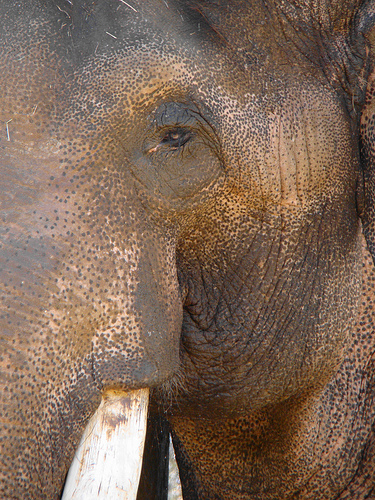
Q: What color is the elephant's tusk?
A: White.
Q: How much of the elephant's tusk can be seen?
A: Half.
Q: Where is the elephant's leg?
A: Right.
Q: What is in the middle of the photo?
A: Eye.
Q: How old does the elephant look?
A: Old.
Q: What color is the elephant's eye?
A: Black.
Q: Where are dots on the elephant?
A: Trunk.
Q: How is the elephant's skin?
A: Wrinkly.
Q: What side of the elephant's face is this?
A: Left.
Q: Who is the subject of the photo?
A: Elephant.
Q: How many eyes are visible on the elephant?
A: One.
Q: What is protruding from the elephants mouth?
A: Tusk.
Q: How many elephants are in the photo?
A: One.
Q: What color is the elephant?
A: Brown.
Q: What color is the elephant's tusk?
A: White.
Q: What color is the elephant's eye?
A: Black.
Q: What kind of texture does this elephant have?
A: Wrinkley.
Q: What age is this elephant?
A: Adult.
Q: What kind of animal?
A: Elephant.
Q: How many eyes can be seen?
A: 1.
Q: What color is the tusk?
A: White.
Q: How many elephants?
A: 1.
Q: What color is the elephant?
A: Gray.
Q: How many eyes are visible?
A: 1.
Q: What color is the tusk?
A: White.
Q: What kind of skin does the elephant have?
A: Wrinkly.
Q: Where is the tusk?
A: Next to the trunk.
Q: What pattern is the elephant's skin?
A: Dots.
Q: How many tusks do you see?
A: One.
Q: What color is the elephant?
A: Brown.